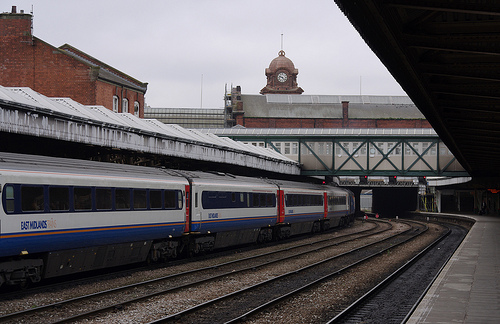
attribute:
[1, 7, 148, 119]
red building — brick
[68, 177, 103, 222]
window — square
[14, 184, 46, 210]
window — square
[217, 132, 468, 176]
bridge — green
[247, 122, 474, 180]
bridge — above the train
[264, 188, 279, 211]
window — square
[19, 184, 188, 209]
window — square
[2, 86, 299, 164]
roof — is white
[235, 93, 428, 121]
roof — grey, under clock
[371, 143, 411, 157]
window — square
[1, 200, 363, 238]
stripe — orange 